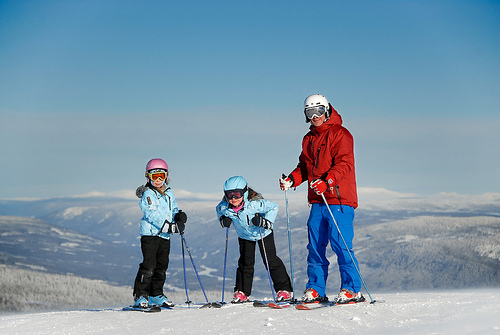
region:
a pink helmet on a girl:
[143, 158, 173, 174]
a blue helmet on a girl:
[220, 174, 249, 199]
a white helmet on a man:
[302, 91, 330, 121]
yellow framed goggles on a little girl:
[145, 169, 172, 185]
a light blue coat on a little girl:
[136, 186, 179, 244]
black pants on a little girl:
[137, 229, 168, 299]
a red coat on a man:
[295, 101, 360, 208]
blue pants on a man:
[303, 203, 361, 295]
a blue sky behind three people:
[1, 0, 499, 198]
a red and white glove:
[309, 179, 330, 197]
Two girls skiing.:
[113, 150, 298, 310]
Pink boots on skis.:
[224, 284, 251, 304]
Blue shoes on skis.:
[130, 294, 168, 309]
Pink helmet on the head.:
[137, 155, 172, 195]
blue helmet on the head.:
[216, 176, 248, 213]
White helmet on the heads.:
[300, 91, 332, 125]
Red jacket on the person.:
[275, 95, 367, 215]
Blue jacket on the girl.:
[210, 170, 283, 243]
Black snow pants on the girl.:
[121, 157, 181, 303]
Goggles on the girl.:
[145, 166, 168, 183]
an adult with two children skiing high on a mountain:
[93, 82, 408, 320]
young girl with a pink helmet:
[126, 137, 198, 319]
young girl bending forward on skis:
[208, 162, 303, 315]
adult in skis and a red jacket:
[268, 85, 380, 315]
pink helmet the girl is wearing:
[147, 157, 168, 169]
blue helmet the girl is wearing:
[222, 177, 246, 189]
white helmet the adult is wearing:
[308, 95, 330, 108]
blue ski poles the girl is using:
[167, 221, 216, 313]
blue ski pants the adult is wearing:
[300, 198, 368, 295]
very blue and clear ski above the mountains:
[7, 8, 258, 143]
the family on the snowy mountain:
[108, 72, 384, 319]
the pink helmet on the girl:
[146, 160, 167, 174]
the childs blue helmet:
[221, 174, 246, 194]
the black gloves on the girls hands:
[168, 208, 269, 233]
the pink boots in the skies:
[224, 287, 295, 308]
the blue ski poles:
[178, 233, 231, 303]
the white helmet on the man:
[302, 90, 332, 124]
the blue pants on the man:
[306, 195, 365, 293]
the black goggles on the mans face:
[303, 104, 326, 119]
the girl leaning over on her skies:
[216, 170, 293, 309]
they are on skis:
[95, 55, 436, 330]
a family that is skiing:
[84, 42, 451, 332]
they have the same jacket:
[111, 104, 311, 333]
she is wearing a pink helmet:
[104, 127, 217, 317]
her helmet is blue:
[206, 137, 302, 319]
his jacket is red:
[263, 57, 418, 329]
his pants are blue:
[245, 53, 410, 334]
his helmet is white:
[268, 69, 408, 334]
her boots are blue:
[121, 260, 188, 334]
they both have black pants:
[115, 114, 292, 314]